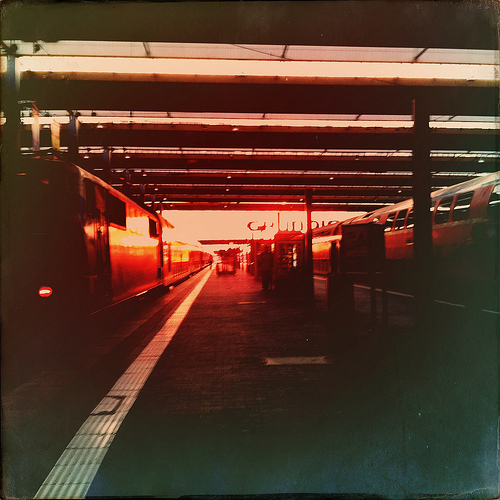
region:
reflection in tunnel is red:
[48, 113, 497, 466]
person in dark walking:
[248, 237, 278, 312]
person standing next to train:
[310, 229, 344, 284]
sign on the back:
[241, 216, 333, 243]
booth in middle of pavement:
[274, 207, 315, 319]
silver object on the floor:
[250, 335, 335, 382]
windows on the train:
[430, 192, 498, 222]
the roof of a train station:
[80, 46, 197, 148]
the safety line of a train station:
[88, 342, 153, 416]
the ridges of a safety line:
[64, 451, 94, 471]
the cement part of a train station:
[154, 389, 275, 471]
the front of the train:
[20, 162, 151, 322]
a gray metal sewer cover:
[252, 338, 339, 388]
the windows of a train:
[364, 195, 491, 240]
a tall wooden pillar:
[378, 102, 445, 329]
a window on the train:
[438, 190, 471, 222]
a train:
[68, 177, 167, 294]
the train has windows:
[438, 198, 470, 219]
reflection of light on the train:
[126, 233, 149, 251]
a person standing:
[329, 233, 341, 273]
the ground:
[219, 301, 276, 335]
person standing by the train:
[328, 240, 339, 270]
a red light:
[36, 284, 52, 298]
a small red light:
[37, 282, 53, 299]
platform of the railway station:
[156, 287, 220, 460]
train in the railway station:
[0, 141, 218, 336]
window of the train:
[436, 192, 478, 222]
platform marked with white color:
[140, 273, 190, 363]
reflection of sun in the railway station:
[162, 221, 214, 275]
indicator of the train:
[32, 284, 67, 304]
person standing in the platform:
[203, 253, 215, 270]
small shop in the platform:
[333, 220, 390, 312]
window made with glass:
[453, 195, 472, 223]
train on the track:
[312, 181, 498, 300]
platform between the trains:
[172, 274, 407, 486]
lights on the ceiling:
[111, 119, 399, 207]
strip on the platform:
[84, 358, 160, 417]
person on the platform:
[243, 243, 268, 286]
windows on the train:
[434, 201, 472, 221]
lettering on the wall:
[236, 215, 351, 234]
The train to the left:
[16, 153, 218, 310]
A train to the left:
[14, 172, 215, 307]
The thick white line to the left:
[31, 262, 276, 497]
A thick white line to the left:
[36, 264, 270, 492]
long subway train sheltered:
[13, 140, 198, 294]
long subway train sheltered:
[9, 135, 223, 329]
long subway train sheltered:
[10, 140, 230, 331]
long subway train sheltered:
[7, 133, 225, 315]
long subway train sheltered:
[1, 140, 222, 329]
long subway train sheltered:
[6, 140, 223, 322]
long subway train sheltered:
[4, 140, 216, 335]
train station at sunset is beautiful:
[7, 115, 497, 445]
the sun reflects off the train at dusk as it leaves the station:
[1, 133, 258, 351]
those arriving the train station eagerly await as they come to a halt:
[259, 177, 495, 332]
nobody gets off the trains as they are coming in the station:
[20, 178, 498, 318]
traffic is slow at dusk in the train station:
[13, 176, 495, 336]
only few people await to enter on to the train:
[252, 189, 497, 320]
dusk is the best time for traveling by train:
[3, 177, 498, 337]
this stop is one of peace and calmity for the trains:
[10, 177, 499, 327]